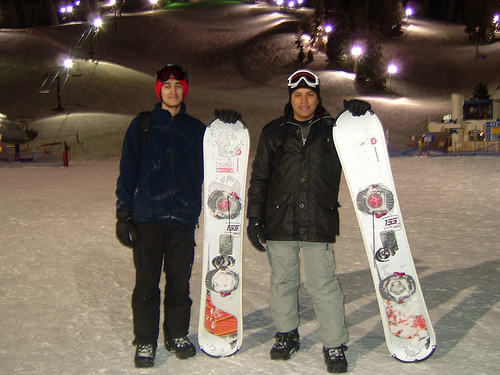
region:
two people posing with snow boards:
[122, 56, 434, 366]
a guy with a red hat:
[124, 59, 206, 371]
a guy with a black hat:
[260, 32, 352, 373]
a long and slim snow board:
[195, 92, 256, 369]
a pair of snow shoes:
[131, 333, 202, 371]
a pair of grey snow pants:
[260, 242, 361, 354]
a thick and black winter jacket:
[247, 98, 359, 255]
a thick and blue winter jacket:
[122, 122, 209, 237]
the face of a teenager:
[155, 68, 193, 116]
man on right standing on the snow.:
[247, 61, 367, 373]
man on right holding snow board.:
[333, 98, 434, 367]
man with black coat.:
[248, 117, 340, 243]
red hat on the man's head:
[148, 63, 193, 98]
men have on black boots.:
[134, 332, 349, 374]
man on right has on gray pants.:
[265, 240, 355, 346]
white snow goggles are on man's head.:
[281, 68, 321, 88]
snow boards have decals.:
[194, 113, 438, 363]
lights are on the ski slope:
[62, 8, 404, 101]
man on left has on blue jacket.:
[121, 110, 206, 217]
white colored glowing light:
[64, 57, 74, 69]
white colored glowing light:
[91, 15, 103, 29]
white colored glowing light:
[58, 5, 68, 14]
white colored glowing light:
[65, 3, 74, 13]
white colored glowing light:
[385, 63, 397, 75]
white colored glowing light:
[348, 43, 363, 60]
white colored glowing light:
[323, 25, 333, 35]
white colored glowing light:
[276, 0, 286, 7]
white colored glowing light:
[287, 0, 295, 10]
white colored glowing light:
[296, 0, 303, 5]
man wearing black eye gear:
[157, 65, 188, 80]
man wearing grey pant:
[270, 250, 340, 332]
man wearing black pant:
[133, 255, 192, 331]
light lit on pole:
[61, 55, 73, 70]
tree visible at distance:
[358, 40, 383, 86]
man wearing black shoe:
[321, 347, 347, 371]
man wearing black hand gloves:
[115, 210, 138, 247]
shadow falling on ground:
[433, 263, 498, 321]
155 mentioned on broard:
[383, 216, 399, 227]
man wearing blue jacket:
[121, 107, 199, 224]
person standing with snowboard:
[135, 54, 249, 368]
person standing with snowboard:
[256, 88, 441, 367]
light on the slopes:
[86, 12, 113, 33]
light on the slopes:
[54, 52, 76, 73]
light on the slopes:
[383, 54, 411, 98]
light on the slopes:
[344, 40, 374, 66]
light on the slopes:
[323, 21, 332, 40]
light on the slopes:
[488, 12, 496, 29]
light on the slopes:
[286, 0, 298, 10]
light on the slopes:
[298, 0, 304, 7]